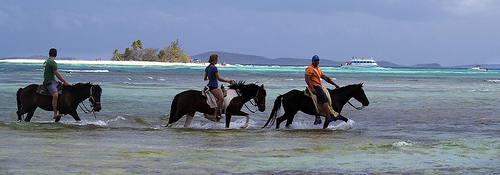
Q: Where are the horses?
A: In water.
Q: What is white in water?
A: Cruise ships.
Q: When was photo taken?
A: Daytime.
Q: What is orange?
A: Shirt.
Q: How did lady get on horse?
A: Mounted up.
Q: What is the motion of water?
A: Waves.